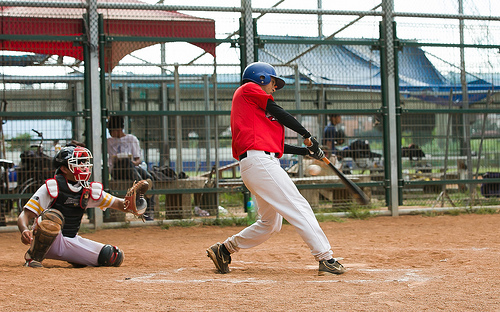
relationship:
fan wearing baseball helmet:
[105, 114, 144, 184] [240, 61, 287, 91]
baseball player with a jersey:
[204, 61, 352, 277] [228, 81, 286, 162]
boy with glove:
[12, 141, 147, 267] [121, 176, 153, 221]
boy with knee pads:
[14, 141, 144, 270] [36, 215, 125, 272]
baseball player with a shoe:
[204, 61, 352, 277] [204, 234, 242, 276]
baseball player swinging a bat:
[206, 63, 346, 274] [316, 150, 368, 203]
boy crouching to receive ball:
[14, 141, 144, 270] [301, 155, 330, 182]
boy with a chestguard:
[14, 141, 144, 270] [42, 166, 99, 246]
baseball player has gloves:
[204, 61, 352, 277] [299, 129, 321, 164]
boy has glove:
[14, 141, 144, 270] [120, 178, 152, 223]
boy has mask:
[14, 141, 144, 270] [65, 147, 95, 179]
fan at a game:
[102, 112, 162, 215] [28, 58, 383, 281]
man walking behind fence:
[322, 109, 344, 156] [7, 1, 496, 226]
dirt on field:
[2, 206, 496, 310] [4, 207, 480, 303]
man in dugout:
[320, 112, 345, 160] [249, 8, 499, 201]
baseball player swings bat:
[204, 61, 352, 277] [295, 137, 404, 219]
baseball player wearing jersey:
[204, 61, 352, 277] [227, 82, 288, 158]